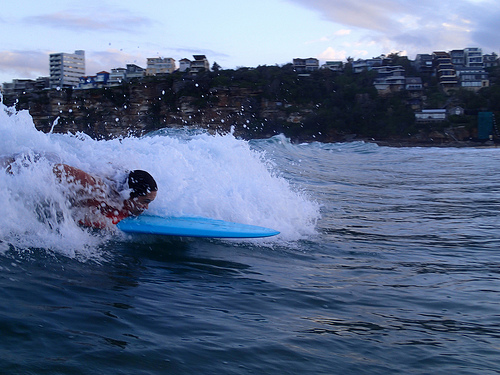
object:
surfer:
[1, 156, 162, 228]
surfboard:
[114, 212, 284, 240]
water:
[258, 128, 489, 374]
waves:
[107, 131, 305, 235]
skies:
[3, 3, 484, 57]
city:
[0, 45, 500, 142]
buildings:
[0, 50, 500, 137]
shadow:
[119, 240, 247, 280]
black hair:
[124, 167, 158, 199]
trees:
[205, 68, 411, 133]